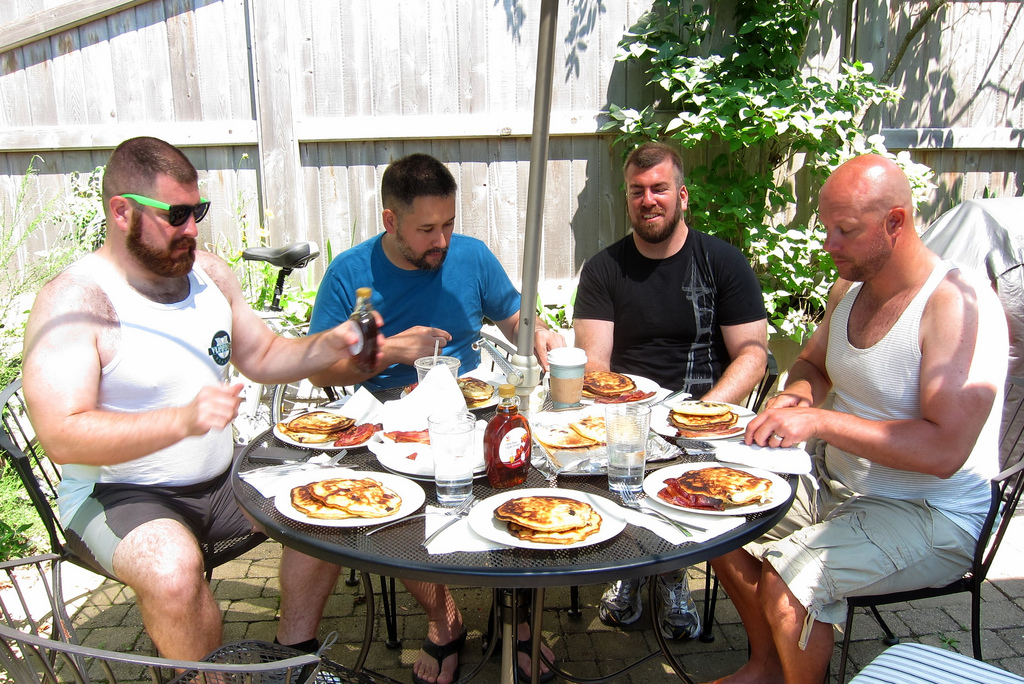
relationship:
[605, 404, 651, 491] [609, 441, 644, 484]
drink of drink